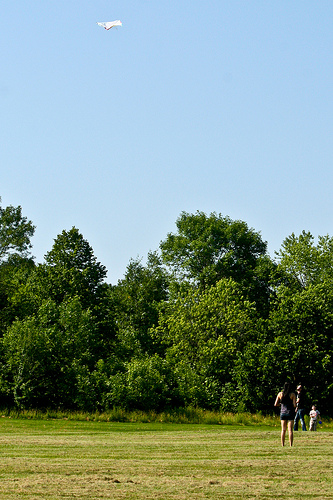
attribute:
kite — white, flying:
[97, 18, 120, 30]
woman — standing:
[273, 380, 296, 442]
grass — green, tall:
[2, 415, 332, 499]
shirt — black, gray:
[277, 393, 294, 412]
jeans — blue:
[294, 409, 311, 427]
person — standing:
[278, 386, 295, 444]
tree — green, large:
[1, 194, 332, 415]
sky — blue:
[3, 6, 332, 288]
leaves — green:
[3, 205, 330, 412]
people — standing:
[276, 384, 312, 445]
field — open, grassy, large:
[2, 416, 332, 499]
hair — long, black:
[282, 380, 292, 401]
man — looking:
[309, 404, 321, 430]